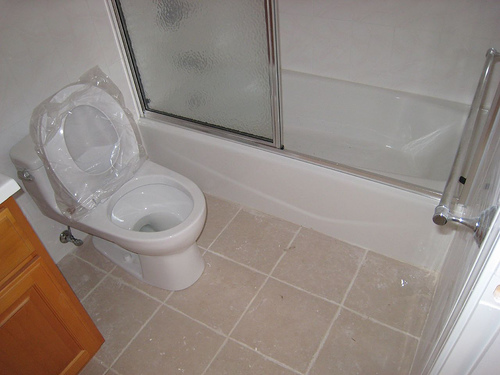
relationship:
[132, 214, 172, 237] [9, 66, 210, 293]
water in toilet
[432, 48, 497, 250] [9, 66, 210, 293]
bar near toilet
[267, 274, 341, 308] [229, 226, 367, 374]
groove between tiles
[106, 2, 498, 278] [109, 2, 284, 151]
shower has door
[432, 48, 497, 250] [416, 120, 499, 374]
bar attatched to wall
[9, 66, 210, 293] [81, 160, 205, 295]
toilet has bowl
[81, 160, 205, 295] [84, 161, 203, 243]
bowl has edge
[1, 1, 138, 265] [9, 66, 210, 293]
wall behind toilet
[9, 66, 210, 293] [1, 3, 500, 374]
toilet in bathroom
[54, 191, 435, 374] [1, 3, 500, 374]
floor in bathroom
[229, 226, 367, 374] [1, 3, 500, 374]
tiles in bathroom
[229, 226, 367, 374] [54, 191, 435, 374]
tiles on floor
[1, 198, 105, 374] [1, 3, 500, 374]
cabinet in bathroom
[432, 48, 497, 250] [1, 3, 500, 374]
bar in bathroom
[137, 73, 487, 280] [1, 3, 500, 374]
bathtub in bathroom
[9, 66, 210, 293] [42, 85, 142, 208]
toilet has lid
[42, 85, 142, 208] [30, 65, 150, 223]
lid has wrapping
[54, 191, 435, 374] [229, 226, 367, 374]
floor has tiles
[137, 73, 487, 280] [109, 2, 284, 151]
bathtub has door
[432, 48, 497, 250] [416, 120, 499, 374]
bar on wall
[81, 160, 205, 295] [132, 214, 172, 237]
bowl has water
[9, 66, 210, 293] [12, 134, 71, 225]
toilet has water source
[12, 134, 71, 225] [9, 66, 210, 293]
water source behind toilet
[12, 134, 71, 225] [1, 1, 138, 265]
water source fastened on wall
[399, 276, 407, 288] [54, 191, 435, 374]
debris on floor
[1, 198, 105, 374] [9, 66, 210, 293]
cabinet next to toilet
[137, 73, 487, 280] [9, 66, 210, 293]
bathtub next to toilet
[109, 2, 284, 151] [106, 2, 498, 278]
door for shower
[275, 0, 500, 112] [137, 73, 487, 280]
tile behind bathtub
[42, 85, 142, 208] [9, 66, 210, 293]
lid on toilet